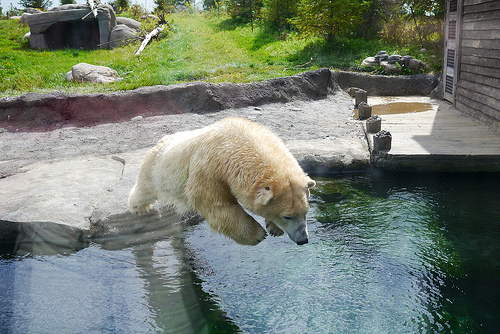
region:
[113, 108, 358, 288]
white bear leaping into pool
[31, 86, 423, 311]
natural looking pool of water with dirt and rock platform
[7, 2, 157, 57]
artificial cave with rectangular opening on hill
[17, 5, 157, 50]
large boulders on either side of cave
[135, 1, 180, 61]
large tree branch laying near cave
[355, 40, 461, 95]
pile of rocks near building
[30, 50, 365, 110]
embankment between grass and dirt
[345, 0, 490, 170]
open patio outside of building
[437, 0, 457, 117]
door with square panels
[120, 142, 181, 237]
bear's leg pushing off of platform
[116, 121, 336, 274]
polar bear is diving into a pool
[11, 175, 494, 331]
a pool of clear water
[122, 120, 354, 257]
a large polar bear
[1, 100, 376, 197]
a rocky ledge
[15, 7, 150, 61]
a rocky cave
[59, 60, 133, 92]
a large rock lies in the grass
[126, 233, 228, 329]
polar bear casts shadow on the water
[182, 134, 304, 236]
polar bear has light brown fur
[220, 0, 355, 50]
row of trees stretching to the horizon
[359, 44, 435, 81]
a pile of rocks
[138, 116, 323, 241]
this is a polar bear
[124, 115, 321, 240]
the polar bear is diving in water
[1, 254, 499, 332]
the water is calm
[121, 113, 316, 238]
the polar bear is cream in color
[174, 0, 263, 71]
grass are behind the bear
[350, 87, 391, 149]
the stones are arranged in a straight line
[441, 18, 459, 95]
the door is closed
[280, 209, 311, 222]
the eyes are closed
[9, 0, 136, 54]
this is a small cave behind the background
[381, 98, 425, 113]
water is on the floor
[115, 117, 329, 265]
a large, happy polar bear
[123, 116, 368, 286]
large bear jumping into the water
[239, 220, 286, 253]
some large black claws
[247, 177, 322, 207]
pair of white ears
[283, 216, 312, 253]
a long white snout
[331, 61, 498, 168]
a rectangular wooden deck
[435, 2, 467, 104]
a wooden slatted door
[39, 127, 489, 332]
a large water feature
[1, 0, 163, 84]
a rock cave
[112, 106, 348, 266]
Bear is about to jump into water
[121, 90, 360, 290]
The bears coat is cream white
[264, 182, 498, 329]
The water is greenish blue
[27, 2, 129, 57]
Bear cave is in the background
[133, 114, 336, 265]
The animal in this image is a polar bear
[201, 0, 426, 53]
Background has tall trees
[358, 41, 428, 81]
Pile of gray rocks are in the background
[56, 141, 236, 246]
Bears back legs are touching the rock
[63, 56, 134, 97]
Large gray stone is in the background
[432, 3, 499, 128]
Gray building is on the right side of photo